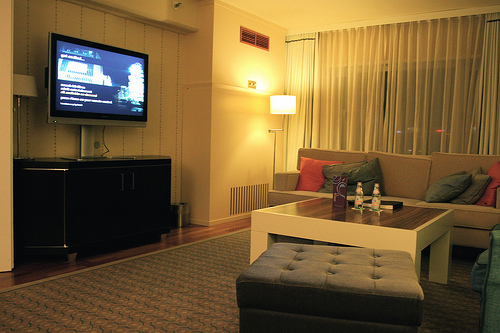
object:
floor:
[0, 223, 495, 333]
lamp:
[267, 95, 298, 174]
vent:
[239, 28, 269, 49]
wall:
[1, 0, 286, 272]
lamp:
[269, 94, 296, 114]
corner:
[268, 22, 304, 190]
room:
[0, 0, 494, 331]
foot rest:
[234, 240, 424, 331]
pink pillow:
[294, 156, 344, 192]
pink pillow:
[475, 163, 498, 206]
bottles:
[355, 180, 381, 211]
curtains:
[283, 11, 500, 154]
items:
[359, 198, 403, 211]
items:
[371, 183, 382, 211]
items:
[353, 181, 365, 212]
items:
[332, 175, 347, 209]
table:
[247, 197, 455, 285]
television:
[44, 31, 151, 128]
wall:
[151, 3, 287, 228]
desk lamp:
[11, 75, 40, 162]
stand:
[13, 154, 173, 266]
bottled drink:
[355, 180, 365, 210]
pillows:
[295, 155, 388, 196]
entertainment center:
[11, 29, 197, 274]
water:
[371, 182, 381, 210]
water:
[353, 181, 364, 211]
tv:
[47, 32, 150, 127]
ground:
[0, 216, 500, 333]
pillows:
[421, 160, 500, 206]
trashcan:
[172, 201, 191, 228]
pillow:
[317, 158, 386, 197]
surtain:
[310, 22, 384, 155]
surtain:
[384, 14, 484, 156]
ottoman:
[232, 239, 425, 331]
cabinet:
[11, 153, 173, 257]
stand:
[64, 125, 117, 162]